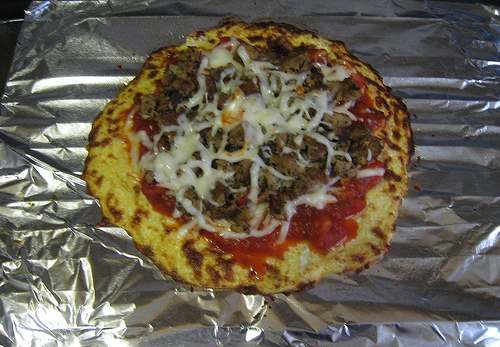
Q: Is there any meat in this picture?
A: Yes, there is meat.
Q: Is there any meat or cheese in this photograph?
A: Yes, there is meat.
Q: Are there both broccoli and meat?
A: No, there is meat but no broccoli.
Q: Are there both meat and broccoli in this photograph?
A: No, there is meat but no broccoli.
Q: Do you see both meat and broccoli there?
A: No, there is meat but no broccoli.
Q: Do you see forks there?
A: No, there are no forks.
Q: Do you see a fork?
A: No, there are no forks.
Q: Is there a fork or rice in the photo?
A: No, there are no forks or rice.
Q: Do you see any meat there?
A: Yes, there is meat.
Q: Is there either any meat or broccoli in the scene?
A: Yes, there is meat.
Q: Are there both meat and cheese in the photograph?
A: Yes, there are both meat and cheese.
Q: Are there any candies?
A: No, there are no candies.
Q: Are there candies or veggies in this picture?
A: No, there are no candies or veggies.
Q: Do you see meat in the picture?
A: Yes, there is meat.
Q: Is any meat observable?
A: Yes, there is meat.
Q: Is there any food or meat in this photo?
A: Yes, there is meat.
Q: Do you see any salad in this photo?
A: No, there is no salad.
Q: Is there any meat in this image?
A: Yes, there is meat.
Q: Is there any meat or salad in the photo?
A: Yes, there is meat.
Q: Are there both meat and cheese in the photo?
A: Yes, there are both meat and cheese.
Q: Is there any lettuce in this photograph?
A: No, there is no lettuce.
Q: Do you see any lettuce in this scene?
A: No, there is no lettuce.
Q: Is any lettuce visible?
A: No, there is no lettuce.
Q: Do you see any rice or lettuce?
A: No, there are no lettuce or rice.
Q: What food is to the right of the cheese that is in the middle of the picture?
A: The food is meat.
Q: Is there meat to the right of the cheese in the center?
A: Yes, there is meat to the right of the cheese.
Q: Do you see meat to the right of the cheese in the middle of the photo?
A: Yes, there is meat to the right of the cheese.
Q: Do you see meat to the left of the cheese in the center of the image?
A: No, the meat is to the right of the cheese.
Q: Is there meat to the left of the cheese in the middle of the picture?
A: No, the meat is to the right of the cheese.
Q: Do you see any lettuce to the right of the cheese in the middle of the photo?
A: No, there is meat to the right of the cheese.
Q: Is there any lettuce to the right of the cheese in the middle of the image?
A: No, there is meat to the right of the cheese.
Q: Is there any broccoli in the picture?
A: No, there is no broccoli.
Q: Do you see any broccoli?
A: No, there is no broccoli.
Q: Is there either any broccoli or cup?
A: No, there are no broccoli or cups.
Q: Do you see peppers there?
A: No, there are no peppers.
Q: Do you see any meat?
A: Yes, there is meat.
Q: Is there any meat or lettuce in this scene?
A: Yes, there is meat.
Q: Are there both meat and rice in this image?
A: No, there is meat but no rice.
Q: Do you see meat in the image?
A: Yes, there is meat.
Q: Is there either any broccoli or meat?
A: Yes, there is meat.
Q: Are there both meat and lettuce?
A: No, there is meat but no lettuce.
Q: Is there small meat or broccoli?
A: Yes, there is small meat.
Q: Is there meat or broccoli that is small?
A: Yes, the meat is small.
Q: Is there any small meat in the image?
A: Yes, there is small meat.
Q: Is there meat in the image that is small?
A: Yes, there is meat that is small.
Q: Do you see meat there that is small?
A: Yes, there is meat that is small.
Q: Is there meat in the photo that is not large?
A: Yes, there is small meat.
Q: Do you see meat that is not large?
A: Yes, there is small meat.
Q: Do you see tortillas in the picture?
A: No, there are no tortillas.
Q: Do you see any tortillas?
A: No, there are no tortillas.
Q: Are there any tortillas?
A: No, there are no tortillas.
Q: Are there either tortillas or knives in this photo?
A: No, there are no tortillas or knives.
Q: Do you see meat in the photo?
A: Yes, there is meat.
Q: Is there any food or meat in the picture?
A: Yes, there is meat.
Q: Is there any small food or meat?
A: Yes, there is small meat.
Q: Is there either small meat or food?
A: Yes, there is small meat.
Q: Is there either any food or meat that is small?
A: Yes, the meat is small.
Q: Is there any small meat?
A: Yes, there is small meat.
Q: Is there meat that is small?
A: Yes, there is meat that is small.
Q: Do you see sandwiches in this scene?
A: No, there are no sandwiches.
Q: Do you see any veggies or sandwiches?
A: No, there are no sandwiches or veggies.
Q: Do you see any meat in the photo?
A: Yes, there is meat.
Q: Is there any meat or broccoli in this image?
A: Yes, there is meat.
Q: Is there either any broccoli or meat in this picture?
A: Yes, there is meat.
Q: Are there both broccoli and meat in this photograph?
A: No, there is meat but no broccoli.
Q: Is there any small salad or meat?
A: Yes, there is small meat.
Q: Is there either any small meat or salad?
A: Yes, there is small meat.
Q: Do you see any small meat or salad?
A: Yes, there is small meat.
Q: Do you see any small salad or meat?
A: Yes, there is small meat.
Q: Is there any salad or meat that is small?
A: Yes, the meat is small.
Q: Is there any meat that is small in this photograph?
A: Yes, there is small meat.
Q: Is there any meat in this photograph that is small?
A: Yes, there is meat that is small.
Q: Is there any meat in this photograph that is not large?
A: Yes, there is small meat.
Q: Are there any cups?
A: No, there are no cups.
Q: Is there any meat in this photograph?
A: Yes, there is meat.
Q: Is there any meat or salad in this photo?
A: Yes, there is meat.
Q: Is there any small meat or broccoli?
A: Yes, there is small meat.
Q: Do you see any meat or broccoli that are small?
A: Yes, the meat is small.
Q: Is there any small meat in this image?
A: Yes, there is small meat.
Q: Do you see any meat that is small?
A: Yes, there is meat that is small.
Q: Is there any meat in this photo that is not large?
A: Yes, there is small meat.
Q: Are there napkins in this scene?
A: No, there are no napkins.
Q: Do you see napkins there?
A: No, there are no napkins.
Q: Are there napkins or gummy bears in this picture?
A: No, there are no napkins or gummy bears.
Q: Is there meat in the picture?
A: Yes, there is meat.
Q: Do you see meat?
A: Yes, there is meat.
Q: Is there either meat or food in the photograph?
A: Yes, there is meat.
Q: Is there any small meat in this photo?
A: Yes, there is small meat.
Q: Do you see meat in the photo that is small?
A: Yes, there is meat that is small.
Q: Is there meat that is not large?
A: Yes, there is small meat.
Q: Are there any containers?
A: No, there are no containers.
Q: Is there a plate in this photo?
A: No, there are no plates.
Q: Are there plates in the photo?
A: No, there are no plates.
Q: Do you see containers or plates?
A: No, there are no plates or containers.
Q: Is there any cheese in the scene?
A: Yes, there is cheese.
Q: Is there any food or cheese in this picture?
A: Yes, there is cheese.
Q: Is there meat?
A: Yes, there is meat.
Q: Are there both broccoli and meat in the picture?
A: No, there is meat but no broccoli.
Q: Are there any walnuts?
A: No, there are no walnuts.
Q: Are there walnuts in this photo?
A: No, there are no walnuts.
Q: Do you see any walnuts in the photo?
A: No, there are no walnuts.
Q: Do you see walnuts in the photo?
A: No, there are no walnuts.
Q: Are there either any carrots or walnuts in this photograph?
A: No, there are no walnuts or carrots.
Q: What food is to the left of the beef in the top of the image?
A: The food is meat.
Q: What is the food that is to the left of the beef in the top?
A: The food is meat.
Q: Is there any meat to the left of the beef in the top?
A: Yes, there is meat to the left of the beef.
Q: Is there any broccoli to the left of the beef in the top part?
A: No, there is meat to the left of the beef.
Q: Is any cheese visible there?
A: Yes, there is cheese.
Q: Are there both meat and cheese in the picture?
A: Yes, there are both cheese and meat.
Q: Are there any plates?
A: No, there are no plates.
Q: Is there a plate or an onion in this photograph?
A: No, there are no plates or onions.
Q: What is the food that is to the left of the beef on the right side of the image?
A: The food is cheese.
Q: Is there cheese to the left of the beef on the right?
A: Yes, there is cheese to the left of the beef.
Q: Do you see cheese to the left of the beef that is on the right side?
A: Yes, there is cheese to the left of the beef.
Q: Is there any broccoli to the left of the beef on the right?
A: No, there is cheese to the left of the beef.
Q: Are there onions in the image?
A: No, there are no onions.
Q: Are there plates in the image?
A: No, there are no plates.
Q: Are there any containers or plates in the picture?
A: No, there are no plates or containers.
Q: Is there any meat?
A: Yes, there is meat.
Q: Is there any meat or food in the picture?
A: Yes, there is meat.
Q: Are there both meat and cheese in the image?
A: Yes, there are both meat and cheese.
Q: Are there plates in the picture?
A: No, there are no plates.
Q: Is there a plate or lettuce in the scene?
A: No, there are no plates or lettuce.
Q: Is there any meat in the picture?
A: Yes, there is meat.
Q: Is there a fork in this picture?
A: No, there are no forks.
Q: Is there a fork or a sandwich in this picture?
A: No, there are no forks or sandwiches.